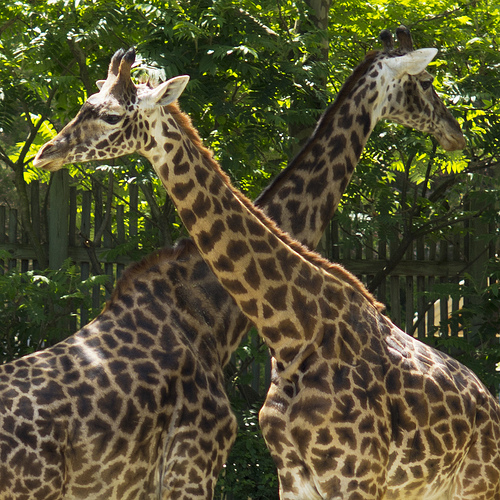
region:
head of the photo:
[32, 58, 175, 179]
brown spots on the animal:
[324, 334, 457, 455]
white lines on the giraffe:
[323, 358, 443, 451]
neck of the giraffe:
[165, 123, 319, 326]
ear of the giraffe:
[142, 58, 197, 123]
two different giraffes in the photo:
[0, 10, 485, 290]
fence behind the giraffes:
[32, 175, 132, 260]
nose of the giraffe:
[435, 94, 471, 154]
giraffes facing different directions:
[27, 43, 471, 300]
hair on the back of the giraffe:
[174, 109, 214, 146]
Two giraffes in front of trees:
[31, 45, 472, 181]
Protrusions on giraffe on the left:
[112, 46, 137, 75]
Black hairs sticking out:
[116, 47, 135, 59]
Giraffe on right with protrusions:
[381, 29, 411, 46]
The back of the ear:
[412, 51, 430, 61]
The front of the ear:
[170, 84, 180, 92]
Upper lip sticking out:
[34, 164, 42, 169]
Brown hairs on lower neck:
[375, 300, 380, 305]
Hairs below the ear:
[170, 105, 176, 111]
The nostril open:
[48, 145, 52, 150]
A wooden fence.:
[1, 163, 498, 342]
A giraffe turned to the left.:
[31, 44, 498, 497]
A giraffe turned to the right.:
[0, 22, 467, 498]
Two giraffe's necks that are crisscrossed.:
[124, 102, 381, 327]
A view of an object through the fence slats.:
[413, 275, 465, 337]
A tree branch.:
[302, 0, 332, 118]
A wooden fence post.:
[44, 167, 74, 291]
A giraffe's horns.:
[101, 41, 138, 83]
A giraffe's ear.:
[148, 73, 191, 112]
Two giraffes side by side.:
[0, 22, 497, 497]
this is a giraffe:
[84, 61, 249, 234]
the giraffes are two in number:
[73, 35, 373, 480]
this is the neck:
[172, 146, 256, 263]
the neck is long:
[168, 147, 290, 295]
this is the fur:
[246, 191, 268, 216]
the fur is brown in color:
[295, 235, 322, 257]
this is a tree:
[212, 38, 279, 118]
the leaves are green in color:
[18, 7, 65, 82]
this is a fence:
[31, 190, 98, 229]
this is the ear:
[144, 72, 196, 108]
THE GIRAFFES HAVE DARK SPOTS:
[2, 25, 497, 497]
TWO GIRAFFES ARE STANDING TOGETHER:
[0, 20, 497, 496]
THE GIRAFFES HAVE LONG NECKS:
[95, 65, 376, 343]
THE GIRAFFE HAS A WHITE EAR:
[375, 41, 435, 86]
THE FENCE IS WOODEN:
[6, 165, 497, 420]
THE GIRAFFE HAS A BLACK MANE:
[157, 92, 388, 324]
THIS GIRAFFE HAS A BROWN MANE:
[75, 50, 375, 300]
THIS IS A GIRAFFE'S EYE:
[90, 106, 141, 138]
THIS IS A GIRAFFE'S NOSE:
[26, 131, 58, 167]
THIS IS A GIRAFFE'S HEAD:
[361, 16, 479, 171]